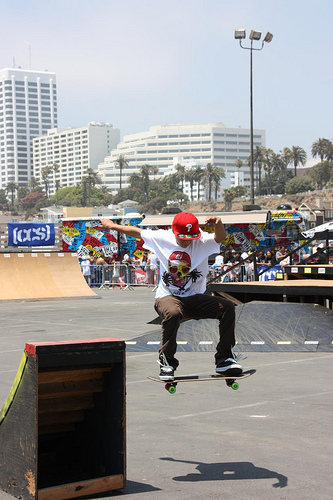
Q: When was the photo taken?
A: Daytime.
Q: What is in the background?
A: Buildings.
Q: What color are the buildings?
A: White.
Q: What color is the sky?
A: Blue.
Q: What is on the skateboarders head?
A: Cap.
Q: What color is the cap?
A: Red.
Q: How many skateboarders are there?
A: One.